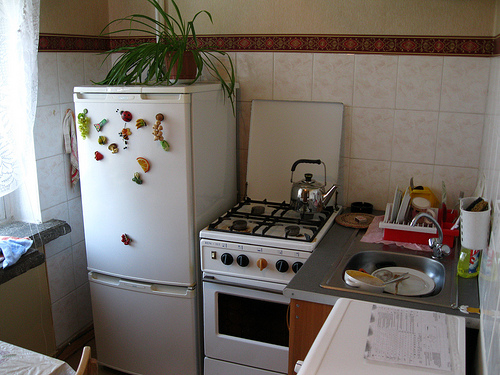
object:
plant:
[94, 1, 244, 85]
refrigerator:
[72, 81, 239, 373]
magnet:
[121, 232, 134, 249]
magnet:
[136, 156, 152, 174]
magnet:
[94, 152, 105, 163]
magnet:
[135, 117, 150, 130]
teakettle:
[290, 158, 339, 216]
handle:
[290, 157, 329, 188]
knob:
[220, 252, 235, 266]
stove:
[200, 197, 345, 374]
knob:
[236, 253, 252, 268]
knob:
[256, 256, 269, 272]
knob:
[274, 257, 291, 273]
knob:
[291, 261, 305, 273]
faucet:
[407, 210, 445, 244]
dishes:
[342, 266, 387, 294]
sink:
[340, 247, 446, 298]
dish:
[397, 186, 414, 225]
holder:
[378, 203, 460, 249]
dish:
[390, 187, 401, 226]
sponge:
[466, 197, 489, 212]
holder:
[457, 194, 493, 252]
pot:
[162, 53, 196, 83]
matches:
[354, 213, 368, 224]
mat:
[336, 210, 376, 229]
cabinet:
[287, 298, 333, 374]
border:
[112, 32, 500, 59]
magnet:
[116, 109, 134, 124]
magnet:
[92, 117, 110, 132]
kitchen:
[0, 1, 500, 374]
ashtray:
[350, 198, 373, 213]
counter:
[283, 204, 482, 326]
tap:
[408, 213, 455, 262]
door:
[72, 96, 198, 288]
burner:
[209, 214, 263, 238]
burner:
[262, 218, 320, 244]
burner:
[232, 194, 281, 218]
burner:
[278, 197, 333, 224]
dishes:
[382, 201, 392, 224]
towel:
[60, 107, 78, 186]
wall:
[22, 1, 500, 349]